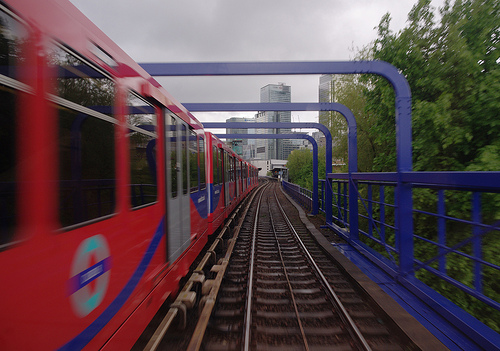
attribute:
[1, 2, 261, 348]
train — red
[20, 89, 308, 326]
train — moving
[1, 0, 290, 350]
train — red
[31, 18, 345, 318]
train — red, on the tracks